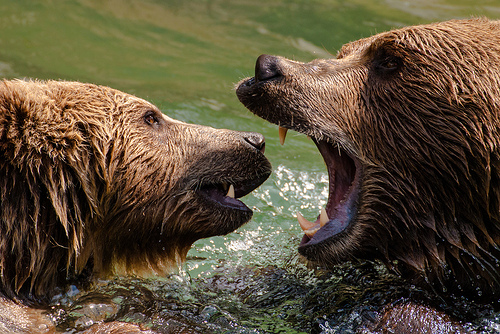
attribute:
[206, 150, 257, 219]
mouth — open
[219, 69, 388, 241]
mouth — open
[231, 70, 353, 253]
mouth — open, wide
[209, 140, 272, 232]
mouth — open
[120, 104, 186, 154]
eyes — brown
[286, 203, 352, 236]
teeth — long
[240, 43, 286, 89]
nose — black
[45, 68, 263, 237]
bear — brown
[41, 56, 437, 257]
bears — brown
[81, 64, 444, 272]
bears — brown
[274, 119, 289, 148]
teeth — white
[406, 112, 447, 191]
fur — wet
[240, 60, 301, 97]
nose — black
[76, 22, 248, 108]
water — calm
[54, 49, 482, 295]
bears — brown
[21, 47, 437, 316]
bears — brown, wrestling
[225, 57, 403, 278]
mouth — open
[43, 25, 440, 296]
bears — fighting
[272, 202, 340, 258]
teeth — bottom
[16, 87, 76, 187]
fur — brown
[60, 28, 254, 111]
water — background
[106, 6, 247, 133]
water — still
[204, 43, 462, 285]
bear — large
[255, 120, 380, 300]
mouth — open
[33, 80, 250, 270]
bear — brown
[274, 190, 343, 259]
tooth — pointy, yellow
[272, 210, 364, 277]
teeth — pointy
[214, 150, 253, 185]
tooth — pointy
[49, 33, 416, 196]
bears — brown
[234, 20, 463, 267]
bear — dark, brown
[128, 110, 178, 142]
eye — brown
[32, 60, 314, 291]
bear — wet, brown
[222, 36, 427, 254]
bear — wet, brown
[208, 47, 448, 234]
bear — brown, furry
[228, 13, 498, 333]
bear — brown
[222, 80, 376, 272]
month — open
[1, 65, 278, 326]
bear — brown, furry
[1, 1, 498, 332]
water — big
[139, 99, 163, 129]
eye — open